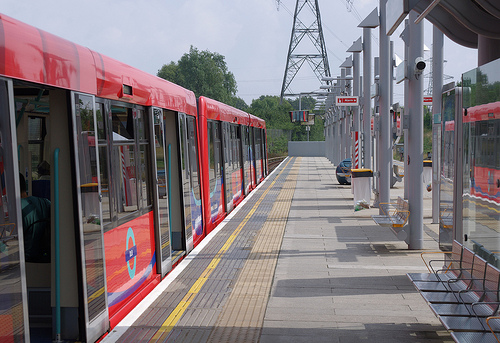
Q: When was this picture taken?
A: During the day.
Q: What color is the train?
A: Red.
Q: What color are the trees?
A: Green.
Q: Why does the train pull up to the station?
A: To let passengers on and off.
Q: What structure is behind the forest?
A: An electrical tower.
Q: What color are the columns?
A: Gray.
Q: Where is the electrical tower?
A: Behind the trees.